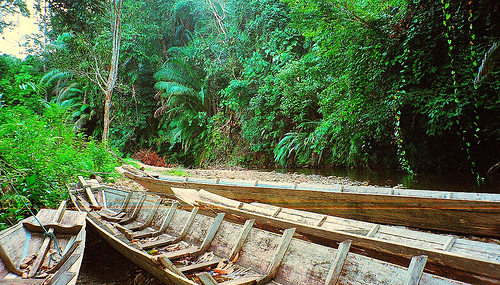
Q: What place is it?
A: It is a forest.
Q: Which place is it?
A: It is a forest.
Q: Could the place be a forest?
A: Yes, it is a forest.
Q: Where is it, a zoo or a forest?
A: It is a forest.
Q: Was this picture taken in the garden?
A: No, the picture was taken in the forest.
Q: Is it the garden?
A: No, it is the forest.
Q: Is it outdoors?
A: Yes, it is outdoors.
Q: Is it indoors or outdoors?
A: It is outdoors.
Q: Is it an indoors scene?
A: No, it is outdoors.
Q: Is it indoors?
A: No, it is outdoors.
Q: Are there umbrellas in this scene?
A: No, there are no umbrellas.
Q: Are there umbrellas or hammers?
A: No, there are no umbrellas or hammers.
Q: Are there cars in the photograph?
A: No, there are no cars.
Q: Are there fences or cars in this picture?
A: No, there are no cars or fences.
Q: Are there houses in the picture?
A: No, there are no houses.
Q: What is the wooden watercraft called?
A: The watercraft is boats.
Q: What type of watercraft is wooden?
A: The watercraft is boats.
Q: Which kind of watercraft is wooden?
A: The watercraft is boats.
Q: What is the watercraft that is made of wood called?
A: The watercraft is boats.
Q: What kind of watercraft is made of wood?
A: The watercraft is boats.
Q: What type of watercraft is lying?
A: The watercraft is boats.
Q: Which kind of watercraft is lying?
A: The watercraft is boats.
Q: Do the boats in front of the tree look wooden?
A: Yes, the boats are wooden.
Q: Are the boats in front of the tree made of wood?
A: Yes, the boats are made of wood.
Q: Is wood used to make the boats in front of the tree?
A: Yes, the boats are made of wood.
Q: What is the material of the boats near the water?
A: The boats are made of wood.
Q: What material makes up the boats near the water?
A: The boats are made of wood.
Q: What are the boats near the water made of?
A: The boats are made of wood.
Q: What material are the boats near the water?
A: The boats are made of wood.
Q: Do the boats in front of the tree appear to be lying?
A: Yes, the boats are lying.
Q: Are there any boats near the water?
A: Yes, there are boats near the water.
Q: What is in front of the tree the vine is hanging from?
A: The boats are in front of the tree.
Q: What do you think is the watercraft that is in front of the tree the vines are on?
A: The watercraft is boats.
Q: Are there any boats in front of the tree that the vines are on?
A: Yes, there are boats in front of the tree.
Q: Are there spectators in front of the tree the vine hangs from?
A: No, there are boats in front of the tree.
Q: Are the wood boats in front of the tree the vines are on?
A: Yes, the boats are in front of the tree.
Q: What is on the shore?
A: The boats are on the shore.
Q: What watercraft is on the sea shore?
A: The watercraft is boats.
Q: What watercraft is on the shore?
A: The watercraft is boats.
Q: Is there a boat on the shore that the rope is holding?
A: Yes, there are boats on the sea shore.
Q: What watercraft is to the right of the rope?
A: The watercraft is boats.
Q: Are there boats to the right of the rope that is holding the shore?
A: Yes, there are boats to the right of the rope.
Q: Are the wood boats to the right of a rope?
A: Yes, the boats are to the right of a rope.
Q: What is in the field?
A: The boats are in the field.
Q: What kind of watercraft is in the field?
A: The watercraft is boats.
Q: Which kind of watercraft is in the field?
A: The watercraft is boats.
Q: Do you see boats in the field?
A: Yes, there are boats in the field.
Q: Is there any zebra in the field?
A: No, there are boats in the field.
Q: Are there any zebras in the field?
A: No, there are boats in the field.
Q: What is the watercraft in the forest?
A: The watercraft is boats.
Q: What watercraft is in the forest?
A: The watercraft is boats.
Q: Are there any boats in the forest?
A: Yes, there are boats in the forest.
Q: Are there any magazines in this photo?
A: No, there are no magazines.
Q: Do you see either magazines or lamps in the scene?
A: No, there are no magazines or lamps.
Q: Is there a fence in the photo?
A: No, there are no fences.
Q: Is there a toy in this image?
A: No, there are no toys.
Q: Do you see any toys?
A: No, there are no toys.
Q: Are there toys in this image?
A: No, there are no toys.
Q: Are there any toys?
A: No, there are no toys.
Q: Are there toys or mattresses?
A: No, there are no toys or mattresses.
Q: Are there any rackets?
A: No, there are no rackets.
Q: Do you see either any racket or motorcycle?
A: No, there are no rackets or motorcycles.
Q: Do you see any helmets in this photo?
A: No, there are no helmets.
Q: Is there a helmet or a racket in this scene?
A: No, there are no helmets or rackets.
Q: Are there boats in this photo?
A: Yes, there is a boat.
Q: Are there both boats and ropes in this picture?
A: Yes, there are both a boat and a rope.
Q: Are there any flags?
A: No, there are no flags.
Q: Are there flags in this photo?
A: No, there are no flags.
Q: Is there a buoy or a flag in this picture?
A: No, there are no flags or buoys.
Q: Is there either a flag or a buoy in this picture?
A: No, there are no flags or buoys.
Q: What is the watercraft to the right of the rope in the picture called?
A: The watercraft is a boat.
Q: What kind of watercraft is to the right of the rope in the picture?
A: The watercraft is a boat.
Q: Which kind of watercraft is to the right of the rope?
A: The watercraft is a boat.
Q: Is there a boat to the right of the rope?
A: Yes, there is a boat to the right of the rope.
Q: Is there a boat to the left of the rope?
A: No, the boat is to the right of the rope.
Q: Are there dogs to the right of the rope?
A: No, there is a boat to the right of the rope.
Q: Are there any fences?
A: No, there are no fences.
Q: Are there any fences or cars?
A: No, there are no fences or cars.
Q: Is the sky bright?
A: Yes, the sky is bright.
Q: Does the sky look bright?
A: Yes, the sky is bright.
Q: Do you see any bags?
A: No, there are no bags.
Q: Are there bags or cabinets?
A: No, there are no bags or cabinets.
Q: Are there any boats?
A: Yes, there is a boat.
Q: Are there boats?
A: Yes, there is a boat.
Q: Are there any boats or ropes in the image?
A: Yes, there is a boat.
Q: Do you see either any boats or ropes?
A: Yes, there is a boat.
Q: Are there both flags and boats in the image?
A: No, there is a boat but no flags.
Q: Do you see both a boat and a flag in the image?
A: No, there is a boat but no flags.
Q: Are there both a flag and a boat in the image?
A: No, there is a boat but no flags.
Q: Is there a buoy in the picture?
A: No, there are no buoys.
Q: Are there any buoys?
A: No, there are no buoys.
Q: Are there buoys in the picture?
A: No, there are no buoys.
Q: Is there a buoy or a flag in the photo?
A: No, there are no buoys or flags.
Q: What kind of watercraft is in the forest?
A: The watercraft is a boat.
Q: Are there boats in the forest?
A: Yes, there is a boat in the forest.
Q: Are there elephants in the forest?
A: No, there is a boat in the forest.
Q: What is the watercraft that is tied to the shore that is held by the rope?
A: The watercraft is a boat.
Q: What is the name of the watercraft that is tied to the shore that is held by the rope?
A: The watercraft is a boat.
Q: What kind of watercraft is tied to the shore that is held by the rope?
A: The watercraft is a boat.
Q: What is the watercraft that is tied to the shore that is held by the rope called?
A: The watercraft is a boat.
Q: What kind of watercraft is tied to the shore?
A: The watercraft is a boat.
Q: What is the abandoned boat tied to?
A: The boat is tied to the sea shore.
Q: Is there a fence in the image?
A: No, there are no fences.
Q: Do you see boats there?
A: Yes, there is a boat.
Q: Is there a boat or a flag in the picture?
A: Yes, there is a boat.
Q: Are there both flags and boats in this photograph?
A: No, there is a boat but no flags.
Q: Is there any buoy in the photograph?
A: No, there are no buoys.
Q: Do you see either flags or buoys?
A: No, there are no buoys or flags.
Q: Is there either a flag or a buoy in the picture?
A: No, there are no buoys or flags.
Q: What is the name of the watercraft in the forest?
A: The watercraft is a boat.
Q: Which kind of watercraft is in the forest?
A: The watercraft is a boat.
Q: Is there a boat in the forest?
A: Yes, there is a boat in the forest.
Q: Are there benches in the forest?
A: No, there is a boat in the forest.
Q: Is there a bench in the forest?
A: No, there is a boat in the forest.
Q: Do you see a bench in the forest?
A: No, there is a boat in the forest.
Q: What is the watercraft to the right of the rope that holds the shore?
A: The watercraft is a boat.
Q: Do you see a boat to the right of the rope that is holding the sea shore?
A: Yes, there is a boat to the right of the rope.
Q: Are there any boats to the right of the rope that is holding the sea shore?
A: Yes, there is a boat to the right of the rope.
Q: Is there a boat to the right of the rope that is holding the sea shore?
A: Yes, there is a boat to the right of the rope.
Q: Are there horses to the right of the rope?
A: No, there is a boat to the right of the rope.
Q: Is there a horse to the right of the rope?
A: No, there is a boat to the right of the rope.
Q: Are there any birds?
A: No, there are no birds.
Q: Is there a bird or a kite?
A: No, there are no birds or kites.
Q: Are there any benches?
A: No, there are no benches.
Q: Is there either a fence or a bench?
A: No, there are no benches or fences.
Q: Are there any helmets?
A: No, there are no helmets.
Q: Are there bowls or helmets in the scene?
A: No, there are no helmets or bowls.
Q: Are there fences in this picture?
A: No, there are no fences.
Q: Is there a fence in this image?
A: No, there are no fences.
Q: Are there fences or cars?
A: No, there are no fences or cars.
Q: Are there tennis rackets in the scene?
A: No, there are no tennis rackets.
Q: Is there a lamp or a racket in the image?
A: No, there are no rackets or lamps.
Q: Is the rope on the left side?
A: Yes, the rope is on the left of the image.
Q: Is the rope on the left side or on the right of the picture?
A: The rope is on the left of the image.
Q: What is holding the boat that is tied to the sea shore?
A: The rope is holding the boat.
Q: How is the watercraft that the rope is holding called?
A: The watercraft is a boat.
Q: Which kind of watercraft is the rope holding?
A: The rope is holding the boat.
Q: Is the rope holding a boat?
A: Yes, the rope is holding a boat.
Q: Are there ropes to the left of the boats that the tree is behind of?
A: Yes, there is a rope to the left of the boats.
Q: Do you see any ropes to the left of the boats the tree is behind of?
A: Yes, there is a rope to the left of the boats.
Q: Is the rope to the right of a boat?
A: No, the rope is to the left of a boat.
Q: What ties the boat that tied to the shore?
A: The rope ties the boat.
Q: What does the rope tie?
A: The rope ties the boat.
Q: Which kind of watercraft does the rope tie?
A: The rope ties the boat.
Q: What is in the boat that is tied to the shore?
A: The rope is in the boat.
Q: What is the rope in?
A: The rope is in the boat.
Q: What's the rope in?
A: The rope is in the boat.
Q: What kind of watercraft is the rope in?
A: The rope is in the boat.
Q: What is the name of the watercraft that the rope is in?
A: The watercraft is a boat.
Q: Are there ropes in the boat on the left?
A: Yes, there is a rope in the boat.